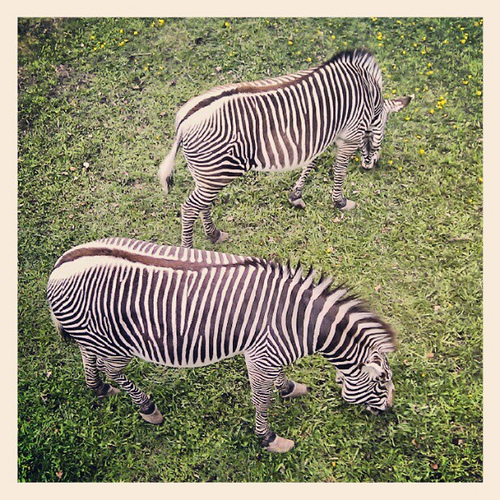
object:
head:
[362, 85, 409, 172]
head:
[340, 360, 395, 414]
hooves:
[264, 432, 293, 453]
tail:
[152, 122, 185, 203]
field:
[16, 17, 482, 481]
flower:
[17, 18, 481, 164]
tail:
[48, 310, 77, 349]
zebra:
[157, 49, 415, 251]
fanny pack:
[417, 27, 483, 117]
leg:
[102, 353, 151, 410]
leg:
[74, 337, 102, 392]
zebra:
[47, 239, 394, 456]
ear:
[363, 360, 387, 380]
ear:
[381, 93, 413, 114]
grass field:
[18, 13, 481, 480]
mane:
[246, 247, 400, 357]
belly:
[112, 284, 243, 365]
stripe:
[49, 241, 286, 275]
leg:
[243, 352, 281, 435]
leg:
[272, 366, 288, 393]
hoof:
[139, 403, 164, 425]